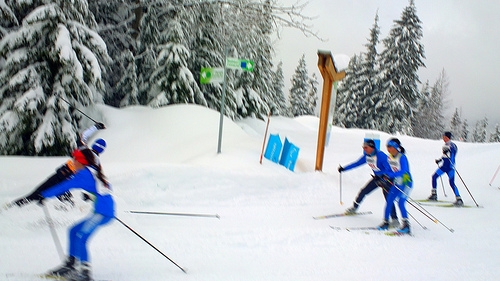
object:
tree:
[330, 0, 434, 138]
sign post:
[312, 77, 335, 171]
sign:
[220, 55, 262, 73]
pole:
[126, 206, 219, 222]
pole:
[379, 172, 458, 233]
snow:
[0, 28, 499, 281]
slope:
[26, 156, 496, 274]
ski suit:
[375, 154, 414, 223]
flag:
[260, 129, 282, 165]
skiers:
[336, 128, 401, 229]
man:
[0, 121, 110, 215]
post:
[211, 71, 229, 153]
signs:
[196, 65, 232, 86]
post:
[311, 72, 330, 173]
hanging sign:
[324, 75, 334, 147]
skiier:
[373, 132, 417, 237]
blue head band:
[385, 140, 402, 150]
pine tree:
[0, 0, 116, 157]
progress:
[0, 117, 499, 279]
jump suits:
[40, 164, 119, 263]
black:
[29, 175, 68, 197]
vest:
[67, 155, 80, 174]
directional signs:
[198, 55, 255, 154]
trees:
[286, 54, 320, 119]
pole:
[213, 66, 227, 153]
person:
[423, 126, 467, 211]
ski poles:
[396, 207, 426, 232]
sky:
[266, 0, 499, 87]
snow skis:
[0, 157, 498, 280]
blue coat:
[377, 153, 415, 189]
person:
[34, 146, 123, 281]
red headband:
[68, 146, 92, 166]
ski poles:
[36, 197, 71, 262]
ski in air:
[117, 86, 170, 128]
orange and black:
[52, 155, 79, 176]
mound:
[104, 101, 244, 168]